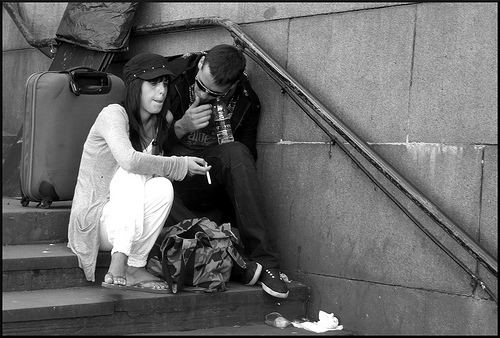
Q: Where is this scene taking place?
A: Outdoor Stairs.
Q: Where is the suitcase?
A: On step behind couple.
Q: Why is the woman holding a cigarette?
A: She is getting ready to light it.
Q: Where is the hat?
A: On woman's head.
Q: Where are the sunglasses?
A: On man's face.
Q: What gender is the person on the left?
A: Female.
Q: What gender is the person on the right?
A: Male.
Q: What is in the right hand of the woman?
A: Cigarette.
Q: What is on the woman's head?
A: Hat.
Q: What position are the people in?
A: Sitting.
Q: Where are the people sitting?
A: Steps.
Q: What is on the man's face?
A: Sunglasses.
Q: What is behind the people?
A: Suitcase.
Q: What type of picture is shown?
A: Black and white.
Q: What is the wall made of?
A: Concrete.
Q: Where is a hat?
A: On woman's head.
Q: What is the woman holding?
A: A cigarette.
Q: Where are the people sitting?
A: Stairs.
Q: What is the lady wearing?
A: Hat.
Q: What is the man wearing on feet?
A: Sneakers.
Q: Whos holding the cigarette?
A: The woman.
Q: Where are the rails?
A: On the wall.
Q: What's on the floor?
A: Paper.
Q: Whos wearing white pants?
A: The woman.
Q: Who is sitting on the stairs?
A: A couple.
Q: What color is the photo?
A: Black and white.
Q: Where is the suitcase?
A: Behind the people.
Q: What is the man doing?
A: Smoking.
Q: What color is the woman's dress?
A: White.